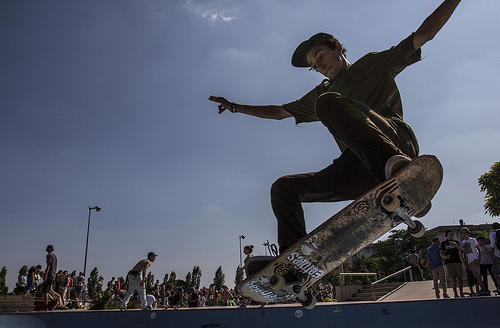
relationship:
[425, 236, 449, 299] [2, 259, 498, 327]
person at skate park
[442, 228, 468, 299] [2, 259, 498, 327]
person at skate park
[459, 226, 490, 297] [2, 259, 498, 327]
person at skate park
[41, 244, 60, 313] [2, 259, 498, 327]
person at skate park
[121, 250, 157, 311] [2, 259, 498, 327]
person at skate park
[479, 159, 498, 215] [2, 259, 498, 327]
tree near skate park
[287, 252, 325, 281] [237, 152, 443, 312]
letters on skateboard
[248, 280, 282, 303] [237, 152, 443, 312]
letters on skateboard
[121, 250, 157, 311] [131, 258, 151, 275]
person without shirt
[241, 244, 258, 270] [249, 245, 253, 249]
girl with bun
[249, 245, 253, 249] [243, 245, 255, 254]
bun in hair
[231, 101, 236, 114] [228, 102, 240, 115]
watch on wrist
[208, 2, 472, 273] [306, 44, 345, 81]
guy has face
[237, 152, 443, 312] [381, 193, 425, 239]
skateboard has wheels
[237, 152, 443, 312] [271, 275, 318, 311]
skateboard has wheels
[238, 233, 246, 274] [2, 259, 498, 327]
light posts near skate park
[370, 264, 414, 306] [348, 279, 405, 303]
rails near stairs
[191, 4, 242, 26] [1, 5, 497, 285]
cloud in sky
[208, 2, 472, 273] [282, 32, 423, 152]
guy has shirt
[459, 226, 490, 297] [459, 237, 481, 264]
person has shirt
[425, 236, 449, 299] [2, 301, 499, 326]
person on ground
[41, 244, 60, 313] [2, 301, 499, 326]
person on ground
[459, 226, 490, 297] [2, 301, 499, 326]
person on ground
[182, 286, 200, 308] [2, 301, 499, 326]
person on ground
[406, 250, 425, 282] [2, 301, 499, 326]
person on ground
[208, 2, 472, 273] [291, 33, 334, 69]
guy wearing cap